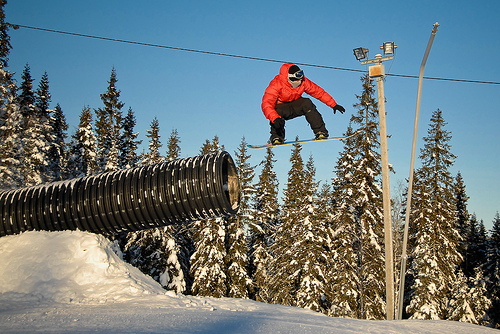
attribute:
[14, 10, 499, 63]
sky — big, white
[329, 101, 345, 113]
glove — black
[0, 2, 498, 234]
sky — blue, big, white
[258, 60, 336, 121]
winter jacket — red, puffy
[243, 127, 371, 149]
snow board — ridden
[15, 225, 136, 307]
snow — white 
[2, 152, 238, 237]
tube — black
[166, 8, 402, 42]
sky — white, big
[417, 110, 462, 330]
tree — green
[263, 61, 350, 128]
jacket — red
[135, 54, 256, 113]
sky — blue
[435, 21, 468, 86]
sky — big, white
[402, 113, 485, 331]
tree — green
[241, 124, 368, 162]
snowboard — high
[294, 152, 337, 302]
tree — green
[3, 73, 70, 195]
tree — green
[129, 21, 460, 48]
sky — white, big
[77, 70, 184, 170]
tree — green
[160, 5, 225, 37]
sky — blue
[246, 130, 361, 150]
snowboard — snow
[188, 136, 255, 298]
tree — green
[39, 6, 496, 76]
sky — blue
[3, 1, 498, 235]
clouds — white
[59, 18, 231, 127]
clouds — white